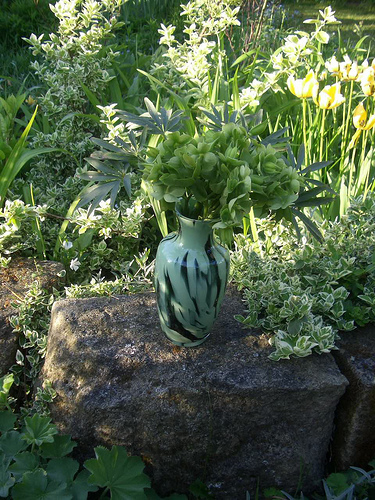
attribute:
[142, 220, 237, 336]
vase — green, glass, shiny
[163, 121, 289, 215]
plants — green, tall, dark green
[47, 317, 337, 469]
rock — gray, big, cracked, stone, large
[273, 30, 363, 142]
flowers — yellow, thin, white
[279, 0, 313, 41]
flowers — purple, blue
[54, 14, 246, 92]
leaves — green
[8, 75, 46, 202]
plants — green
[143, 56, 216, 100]
plants — white